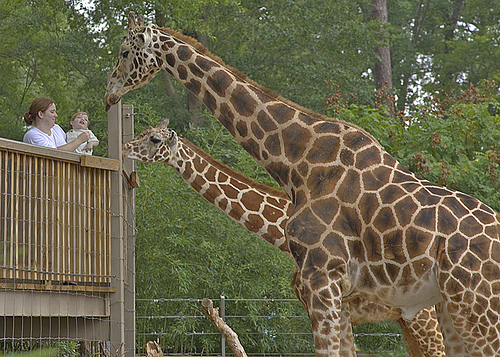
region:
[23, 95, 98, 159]
mom and son looking at the giraffe.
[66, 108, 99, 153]
a baby wearing a white shirt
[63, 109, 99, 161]
a baby with red hair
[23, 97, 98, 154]
a woman holding a baby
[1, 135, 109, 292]
brown colored wooden railing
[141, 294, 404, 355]
three strands of barbed wire fence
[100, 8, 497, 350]
a brown and tan giraffe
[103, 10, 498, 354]
a large male giraffe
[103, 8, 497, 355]
two giraffes looking at the people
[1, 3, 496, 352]
trees are behind the fence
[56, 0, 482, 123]
the sky can be seen through the tree branches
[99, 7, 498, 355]
a giraffe with it's tongue out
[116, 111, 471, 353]
a giraffe trying to eat some food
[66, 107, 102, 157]
a small smiling child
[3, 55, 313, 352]
a bunch of bamboo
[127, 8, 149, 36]
horns on a giraffe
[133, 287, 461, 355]
a metal wire fence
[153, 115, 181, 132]
horns on a giraffe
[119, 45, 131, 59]
a black giraffe eye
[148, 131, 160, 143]
a black giraffe eye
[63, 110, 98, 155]
Child in mother's arms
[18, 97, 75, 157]
Woman holding a child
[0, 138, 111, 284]
Wooden fence in front of people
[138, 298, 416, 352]
Metal fence behind giraffes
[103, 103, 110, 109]
Giraffe's tongue sticking out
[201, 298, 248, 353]
Cut tree branch in a giraffe's pen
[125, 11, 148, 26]
Horns on a giraffe's head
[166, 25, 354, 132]
Hair on a giraffe's neck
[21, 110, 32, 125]
Woman's hair in a ponytail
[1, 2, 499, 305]
Trees behind giraffes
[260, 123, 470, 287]
the giraffe is dirty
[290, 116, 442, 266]
the giraffe is brown and white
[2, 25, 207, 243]
they are near the people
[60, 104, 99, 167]
woman holding a child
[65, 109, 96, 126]
the child looks afraid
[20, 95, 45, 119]
hair is in a bun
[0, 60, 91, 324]
standing on a balcony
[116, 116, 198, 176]
the giraffe is looking at the child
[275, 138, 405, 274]
giraffe has black spots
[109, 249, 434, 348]
the giraffes are fenced in